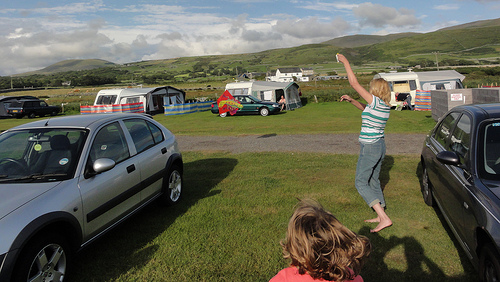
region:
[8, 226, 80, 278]
Left front tire of the silver car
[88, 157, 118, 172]
Driver's side rear view mirror of the silver car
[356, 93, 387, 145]
Woman's green and white striped shirt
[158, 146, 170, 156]
Rear door handle on the silver car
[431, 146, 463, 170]
Passenger side mirror on the black car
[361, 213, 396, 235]
Woman's bare feet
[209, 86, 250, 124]
Multi-colored kite the woman is flying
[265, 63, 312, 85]
Two-story white house way off in the distance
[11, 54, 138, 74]
Mountain far off in the distance to the left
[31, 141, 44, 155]
Round yellow item hanging from the rear view mirror inside the silver car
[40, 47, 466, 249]
people outdoors with cars and tents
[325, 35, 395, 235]
woman holding object from her raised hand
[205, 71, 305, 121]
person sitting in tent behind car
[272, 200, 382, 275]
female with shiny hair curled at ends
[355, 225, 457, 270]
shadow of person with hands to head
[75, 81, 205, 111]
striped fencing around a large tent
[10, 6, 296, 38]
grey and white clouds against blue sky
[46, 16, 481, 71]
hills and mountains behind lot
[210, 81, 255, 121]
red and yellow kite leaning against green car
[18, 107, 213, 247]
grey car with stripes across the doors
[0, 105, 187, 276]
SILVER CAR PARKED ON GRASS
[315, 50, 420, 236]
LADY DIRECTING KITE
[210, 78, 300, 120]
TRAILER AND TENT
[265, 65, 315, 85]
WHITE AND BLACK HOUSE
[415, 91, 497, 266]
BLACK CAR PARKED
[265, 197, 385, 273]
CHILD PLAYING WITH LADY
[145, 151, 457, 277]
GRASS ON THE GROUND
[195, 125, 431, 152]
TAR COVERED ROAD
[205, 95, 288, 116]
GREEN CAR PARKED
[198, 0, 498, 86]
GREEN MOUNTAINS COVERED WITH GRASS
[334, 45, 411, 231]
A woman in a striped shirt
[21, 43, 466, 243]
Campers at a camp ground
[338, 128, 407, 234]
A barefoot person on grass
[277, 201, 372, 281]
A person with brown hair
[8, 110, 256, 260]
A car parked in a grassy area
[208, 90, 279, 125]
A car covered by a sheet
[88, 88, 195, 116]
Camping gear set up in a camp ground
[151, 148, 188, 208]
Tire on a silver car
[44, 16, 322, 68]
Clouds above a mountain range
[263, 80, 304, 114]
A camper in his tent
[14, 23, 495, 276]
People camping outdoor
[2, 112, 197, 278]
Tan car parking on grass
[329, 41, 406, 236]
Barefoot woman with hands up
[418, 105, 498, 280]
Black car next to a barefoot woman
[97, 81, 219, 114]
Camping tent behind a green car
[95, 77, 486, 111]
Camping tents on grass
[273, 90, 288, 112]
Man sitting in a tent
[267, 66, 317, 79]
Two floor house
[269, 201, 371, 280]
Blonde woman sitting between a tan and black car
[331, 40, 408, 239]
woman holding a cup